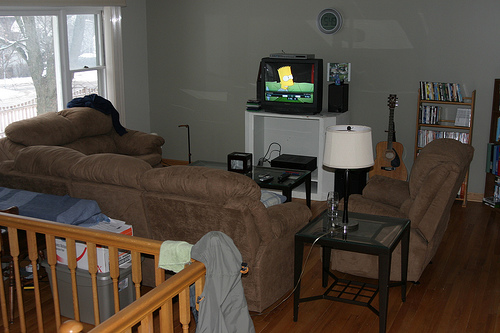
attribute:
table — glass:
[321, 184, 399, 313]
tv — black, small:
[205, 46, 342, 118]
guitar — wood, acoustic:
[372, 95, 406, 184]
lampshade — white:
[300, 125, 370, 170]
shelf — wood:
[397, 71, 480, 224]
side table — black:
[204, 152, 315, 223]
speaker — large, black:
[317, 81, 358, 125]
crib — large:
[4, 210, 232, 329]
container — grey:
[39, 262, 144, 333]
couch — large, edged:
[5, 95, 328, 293]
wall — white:
[133, 11, 498, 188]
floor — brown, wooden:
[403, 211, 498, 324]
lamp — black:
[335, 125, 386, 247]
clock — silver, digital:
[317, 4, 337, 37]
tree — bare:
[0, 12, 60, 116]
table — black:
[183, 141, 327, 222]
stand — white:
[233, 100, 344, 216]